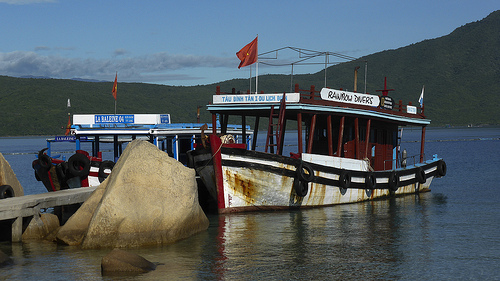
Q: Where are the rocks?
A: By the dock.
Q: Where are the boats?
A: In the water.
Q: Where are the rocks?
A: In the water.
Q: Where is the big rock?
A: In the water.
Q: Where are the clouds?
A: Sky.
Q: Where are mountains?
A: In the distance.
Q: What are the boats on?
A: The lake.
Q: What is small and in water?
A: The tour boat.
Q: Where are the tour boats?
A: At the dock.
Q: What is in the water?
A: A large boulder.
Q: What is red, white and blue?
A: Tour boats.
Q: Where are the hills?
A: Behind the boats.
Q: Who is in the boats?
A: No people.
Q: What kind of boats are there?
A: Tour boats.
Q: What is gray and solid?
A: The boulder.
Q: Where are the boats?
A: In the water.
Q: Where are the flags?
A: On the boats.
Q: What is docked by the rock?
A: A boat.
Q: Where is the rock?
A: By the dock.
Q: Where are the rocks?
A: In the lake.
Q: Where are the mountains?
A: Behind the water.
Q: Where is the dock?
A: By the boats.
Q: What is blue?
A: Sky.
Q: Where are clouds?
A: In the sky.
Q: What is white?
A: Boat.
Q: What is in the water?
A: Boats.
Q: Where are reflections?
A: On the water.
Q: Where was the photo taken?
A: At a boat dock.